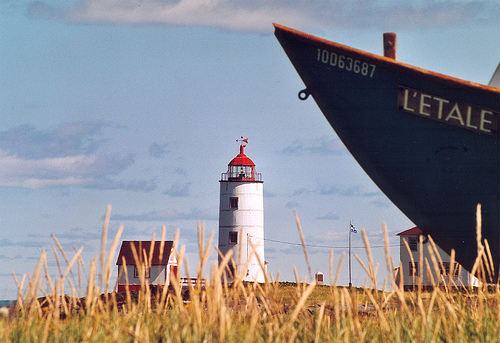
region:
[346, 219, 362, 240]
flag flying on top of flagpole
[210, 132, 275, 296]
red and white light house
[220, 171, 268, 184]
hand railing at top of light house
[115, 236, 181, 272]
red roof on top of a house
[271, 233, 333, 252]
power line hanging between two poles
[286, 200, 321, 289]
a brown piece of grass in a field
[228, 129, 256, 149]
a weather vein on top of light house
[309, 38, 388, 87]
a number painted in white on the front of a boat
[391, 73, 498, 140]
L'ETALE painted on a boat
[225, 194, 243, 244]
two windows on a white light house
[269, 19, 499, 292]
Bow area of the blue Boat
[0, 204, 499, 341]
Dry grass on the field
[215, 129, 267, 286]
White lighthouse on the field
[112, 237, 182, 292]
Small house next to the light house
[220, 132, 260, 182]
Red roof housing of the light house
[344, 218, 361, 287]
Flag near the light house in the field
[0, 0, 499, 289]
Cloudy sky in the background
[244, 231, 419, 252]
Pole line near the light house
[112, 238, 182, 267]
Red roof of the house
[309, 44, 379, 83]
Serial number of a boat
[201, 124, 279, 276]
White light tower in the distance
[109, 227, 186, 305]
House in the distance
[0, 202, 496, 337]
Plants are near the camera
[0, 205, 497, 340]
The plants are yellow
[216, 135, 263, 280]
A light house building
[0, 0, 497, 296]
Sky is mostly clear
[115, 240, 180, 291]
Red and white building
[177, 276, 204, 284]
A red wooden fence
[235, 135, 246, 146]
Weather vane is red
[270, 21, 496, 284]
Front of a ship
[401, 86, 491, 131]
Text says L'Etale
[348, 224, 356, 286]
Flag on a pole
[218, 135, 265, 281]
A lighthouse on the hill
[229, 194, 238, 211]
A window on the lighthouse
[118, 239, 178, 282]
A small building by the lighthouse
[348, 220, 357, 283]
A flagpole near the lighthouse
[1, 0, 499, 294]
The sky above the lighthouse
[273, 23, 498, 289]
A boat near the lighthouse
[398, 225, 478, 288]
A house by the flagpole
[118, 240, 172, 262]
The roof of the small building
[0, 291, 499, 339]
Grass around the lighthouse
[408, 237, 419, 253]
A window on the house